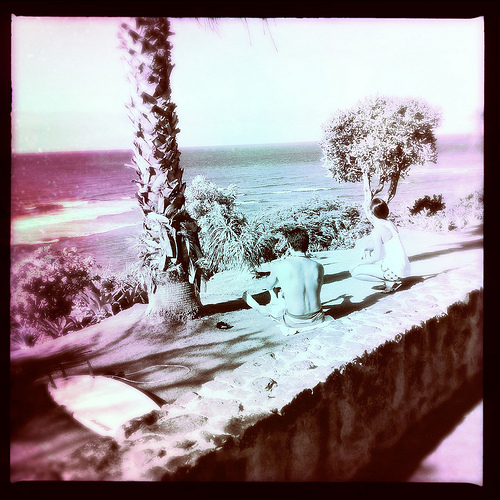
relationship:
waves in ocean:
[11, 193, 141, 242] [12, 141, 481, 269]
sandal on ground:
[209, 319, 236, 333] [9, 239, 432, 481]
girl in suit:
[347, 198, 411, 294] [366, 220, 405, 288]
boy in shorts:
[240, 226, 322, 331] [275, 309, 326, 330]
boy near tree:
[240, 226, 322, 331] [121, 16, 214, 336]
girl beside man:
[347, 198, 411, 294] [236, 223, 328, 327]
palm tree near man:
[114, 16, 214, 339] [236, 223, 328, 327]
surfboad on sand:
[41, 355, 166, 445] [12, 230, 440, 477]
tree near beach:
[318, 93, 442, 234] [1, 175, 484, 482]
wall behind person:
[11, 261, 484, 481] [236, 221, 331, 330]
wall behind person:
[11, 261, 484, 481] [340, 197, 410, 294]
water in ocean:
[13, 192, 134, 247] [12, 137, 483, 282]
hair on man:
[286, 227, 311, 252] [236, 223, 328, 327]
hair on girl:
[369, 196, 390, 220] [347, 198, 411, 294]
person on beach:
[236, 221, 331, 330] [1, 175, 484, 482]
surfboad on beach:
[41, 355, 166, 445] [1, 175, 484, 482]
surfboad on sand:
[41, 355, 166, 445] [2, 232, 465, 465]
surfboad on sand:
[41, 355, 166, 445] [10, 227, 482, 482]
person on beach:
[236, 221, 331, 330] [0, 226, 499, 498]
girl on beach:
[347, 198, 411, 294] [0, 226, 499, 498]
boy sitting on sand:
[240, 226, 322, 331] [10, 227, 482, 482]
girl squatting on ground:
[347, 198, 411, 294] [8, 226, 483, 480]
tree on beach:
[318, 93, 440, 205] [8, 227, 484, 481]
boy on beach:
[240, 226, 322, 331] [8, 205, 482, 476]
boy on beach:
[240, 226, 322, 331] [0, 226, 499, 498]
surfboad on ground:
[41, 355, 166, 445] [8, 226, 483, 480]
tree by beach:
[183, 172, 271, 283] [8, 227, 484, 481]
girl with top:
[347, 198, 411, 294] [364, 204, 420, 272]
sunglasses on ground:
[315, 289, 352, 318] [178, 296, 244, 349]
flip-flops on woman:
[357, 262, 403, 287] [301, 184, 421, 294]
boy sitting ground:
[240, 226, 322, 331] [151, 335, 234, 361]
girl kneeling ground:
[347, 198, 411, 294] [342, 287, 355, 293]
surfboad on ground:
[41, 355, 166, 445] [147, 338, 224, 373]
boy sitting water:
[240, 226, 322, 331] [215, 140, 335, 216]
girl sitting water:
[347, 198, 411, 294] [214, 146, 296, 196]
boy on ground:
[240, 226, 322, 331] [197, 343, 246, 367]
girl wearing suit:
[347, 198, 411, 294] [366, 220, 405, 288]